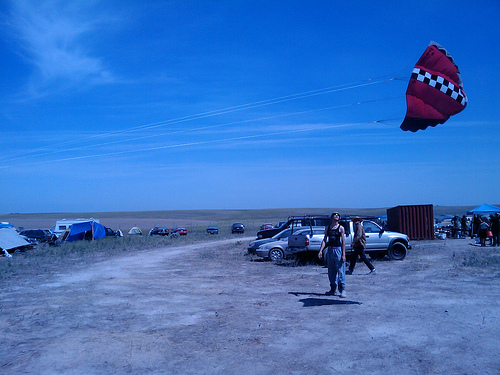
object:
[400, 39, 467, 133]
parachute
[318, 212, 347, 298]
woman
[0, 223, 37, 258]
tent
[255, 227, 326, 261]
car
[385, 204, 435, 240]
container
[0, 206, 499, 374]
ground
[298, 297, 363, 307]
shadow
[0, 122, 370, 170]
strings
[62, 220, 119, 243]
tent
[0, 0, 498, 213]
sky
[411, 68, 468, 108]
checkered pattern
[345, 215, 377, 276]
person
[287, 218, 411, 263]
truck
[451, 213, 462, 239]
person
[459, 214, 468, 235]
person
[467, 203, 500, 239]
gazebo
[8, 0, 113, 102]
cloud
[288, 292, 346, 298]
shadow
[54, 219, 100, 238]
camper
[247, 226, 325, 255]
car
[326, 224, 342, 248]
tank top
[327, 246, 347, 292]
blue pants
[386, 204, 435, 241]
dumpster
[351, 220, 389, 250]
door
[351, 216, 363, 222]
hat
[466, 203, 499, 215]
canopy